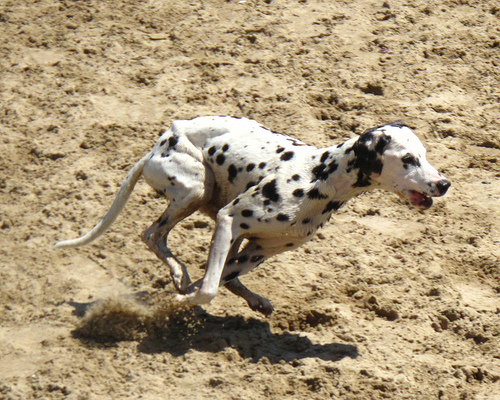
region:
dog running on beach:
[67, 110, 451, 305]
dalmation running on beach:
[34, 110, 460, 308]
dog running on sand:
[44, 117, 454, 288]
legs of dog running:
[137, 220, 288, 324]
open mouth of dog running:
[401, 176, 448, 210]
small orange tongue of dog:
[409, 188, 425, 203]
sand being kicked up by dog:
[72, 297, 188, 325]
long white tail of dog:
[57, 157, 153, 251]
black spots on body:
[248, 166, 305, 208]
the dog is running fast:
[47, 108, 452, 308]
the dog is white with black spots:
[48, 113, 455, 324]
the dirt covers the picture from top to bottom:
[0, 3, 498, 394]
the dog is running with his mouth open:
[52, 111, 454, 328]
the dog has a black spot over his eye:
[52, 109, 451, 316]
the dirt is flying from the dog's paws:
[71, 293, 209, 346]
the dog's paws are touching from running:
[48, 111, 454, 328]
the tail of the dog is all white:
[47, 110, 457, 312]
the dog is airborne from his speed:
[50, 105, 452, 317]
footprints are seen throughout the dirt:
[4, 29, 498, 394]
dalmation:
[74, 115, 436, 332]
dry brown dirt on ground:
[24, 50, 75, 107]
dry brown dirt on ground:
[185, 29, 256, 73]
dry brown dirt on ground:
[153, 48, 231, 119]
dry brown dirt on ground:
[433, 22, 484, 55]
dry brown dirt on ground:
[348, 232, 439, 282]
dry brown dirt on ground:
[358, 266, 463, 348]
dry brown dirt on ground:
[101, 334, 211, 398]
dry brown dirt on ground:
[19, 138, 70, 189]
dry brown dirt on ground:
[64, 36, 147, 94]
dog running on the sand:
[54, 115, 449, 316]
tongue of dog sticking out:
[412, 188, 422, 205]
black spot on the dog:
[281, 150, 293, 158]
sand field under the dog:
[1, 1, 498, 398]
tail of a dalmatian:
[53, 149, 152, 249]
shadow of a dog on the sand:
[67, 291, 358, 361]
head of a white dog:
[369, 124, 450, 209]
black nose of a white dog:
[438, 178, 450, 191]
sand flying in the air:
[78, 300, 201, 342]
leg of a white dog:
[165, 184, 275, 307]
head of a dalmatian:
[355, 123, 449, 212]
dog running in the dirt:
[53, 115, 450, 315]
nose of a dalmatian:
[437, 179, 449, 189]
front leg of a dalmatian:
[168, 182, 281, 314]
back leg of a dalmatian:
[139, 152, 213, 294]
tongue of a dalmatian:
[411, 190, 421, 206]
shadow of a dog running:
[63, 305, 357, 362]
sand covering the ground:
[0, 1, 499, 398]